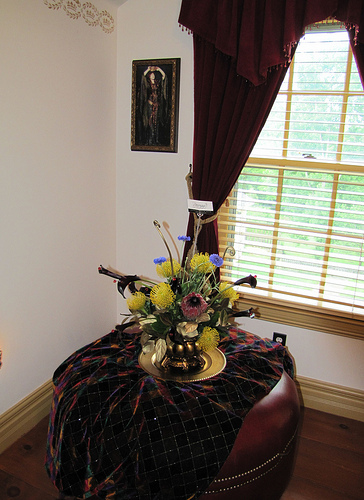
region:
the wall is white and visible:
[18, 133, 91, 225]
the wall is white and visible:
[17, 122, 61, 187]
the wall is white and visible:
[13, 170, 106, 264]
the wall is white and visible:
[28, 91, 136, 243]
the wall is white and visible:
[4, 199, 117, 325]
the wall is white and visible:
[3, 86, 84, 183]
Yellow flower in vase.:
[143, 272, 178, 324]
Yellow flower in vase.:
[121, 290, 158, 335]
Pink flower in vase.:
[179, 289, 216, 337]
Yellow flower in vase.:
[203, 325, 243, 379]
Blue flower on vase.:
[209, 247, 228, 273]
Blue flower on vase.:
[153, 252, 180, 287]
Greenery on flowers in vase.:
[167, 278, 225, 312]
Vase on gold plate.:
[155, 347, 240, 395]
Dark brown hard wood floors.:
[307, 440, 334, 490]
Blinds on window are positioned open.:
[286, 262, 331, 297]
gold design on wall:
[44, 0, 116, 34]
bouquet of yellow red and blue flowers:
[96, 197, 261, 383]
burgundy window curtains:
[176, 0, 363, 262]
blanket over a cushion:
[45, 326, 306, 499]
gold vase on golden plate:
[136, 333, 229, 383]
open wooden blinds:
[219, 27, 363, 313]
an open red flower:
[180, 291, 208, 323]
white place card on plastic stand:
[186, 197, 214, 250]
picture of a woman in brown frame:
[128, 56, 181, 153]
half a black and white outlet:
[272, 330, 287, 344]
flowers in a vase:
[87, 191, 270, 390]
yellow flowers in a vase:
[117, 273, 176, 318]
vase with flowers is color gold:
[154, 323, 210, 380]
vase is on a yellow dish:
[126, 321, 231, 385]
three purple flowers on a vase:
[150, 228, 230, 269]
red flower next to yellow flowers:
[151, 278, 217, 327]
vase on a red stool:
[33, 218, 313, 497]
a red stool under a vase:
[198, 369, 323, 499]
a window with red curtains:
[175, 4, 362, 344]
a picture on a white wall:
[123, 49, 186, 157]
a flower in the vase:
[124, 288, 153, 323]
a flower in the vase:
[148, 275, 174, 315]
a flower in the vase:
[181, 289, 208, 319]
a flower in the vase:
[193, 322, 216, 344]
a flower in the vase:
[157, 258, 187, 282]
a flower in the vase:
[192, 251, 222, 278]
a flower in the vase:
[219, 283, 244, 304]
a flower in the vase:
[204, 243, 228, 272]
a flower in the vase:
[151, 252, 169, 272]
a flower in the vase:
[211, 251, 231, 271]